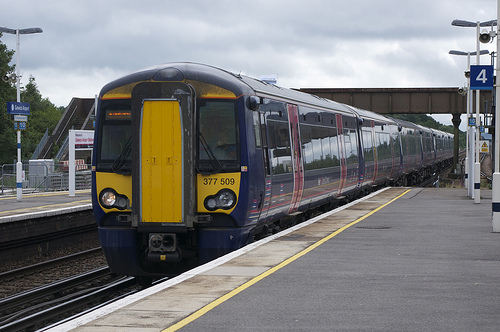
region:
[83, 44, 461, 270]
A passenger train sitting at a train station.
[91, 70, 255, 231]
Yellow sections on the front of the train.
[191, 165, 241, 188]
The number 377 509 on the front of the train.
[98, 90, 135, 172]
Windshield on the left side of the train.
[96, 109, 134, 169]
Windshield wiper on the left side of the train.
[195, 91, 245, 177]
Windshield on the right side of the train.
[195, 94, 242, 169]
Windshield wiper on the right side of the train.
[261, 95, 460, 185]
Passenger windows on the train.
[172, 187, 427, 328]
A yellow line painted on the platform.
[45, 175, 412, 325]
A white line painted on the edge of the platform.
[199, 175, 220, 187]
number 377 on the train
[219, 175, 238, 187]
number 509 on the train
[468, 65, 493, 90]
number 4 on a blue sign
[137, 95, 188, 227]
yellow door on the front of the train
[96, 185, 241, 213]
headlights on the the train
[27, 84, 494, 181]
crosswalk near a platform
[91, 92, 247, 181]
windshield on the front of a train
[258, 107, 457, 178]
windows on the side of the train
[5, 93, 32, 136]
signs on a white pole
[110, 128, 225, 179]
black windshield wipers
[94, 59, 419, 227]
yellow black and red train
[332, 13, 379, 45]
white clouds in blue sky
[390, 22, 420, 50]
white clouds in blue sky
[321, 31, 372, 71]
white clouds in blue sky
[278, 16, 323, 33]
white clouds in blue sky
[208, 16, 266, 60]
white clouds in blue sky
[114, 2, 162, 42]
white clouds in blue sky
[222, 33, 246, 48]
white clouds in blue sky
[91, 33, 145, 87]
white clouds in blue sky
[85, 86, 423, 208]
black and yellow train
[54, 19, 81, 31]
white clouds in blue sky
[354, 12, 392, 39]
white clouds in blue sky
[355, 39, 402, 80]
white clouds in blue sky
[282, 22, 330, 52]
white clouds in blue sky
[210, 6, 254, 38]
white clouds in blue sky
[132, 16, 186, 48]
white clouds in blue sky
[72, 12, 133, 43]
white clouds in blue sky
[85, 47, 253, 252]
front end of train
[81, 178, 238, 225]
front lights of train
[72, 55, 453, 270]
big long passenger train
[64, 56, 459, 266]
full size passenger train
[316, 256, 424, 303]
patch of pavement area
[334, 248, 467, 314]
patch of cement pavement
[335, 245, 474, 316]
patch of gray cement area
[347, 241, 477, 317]
patch of gray pavement area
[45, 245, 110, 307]
area of train tracks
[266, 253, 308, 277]
yellow line area on ground